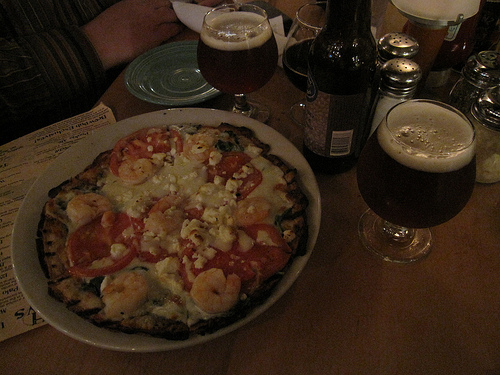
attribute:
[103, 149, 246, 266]
cheese — white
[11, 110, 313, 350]
plate — green, round, white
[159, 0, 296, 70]
napkin — folded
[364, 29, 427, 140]
shaker — pepper, salt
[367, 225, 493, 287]
table — wood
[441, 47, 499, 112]
shaker — black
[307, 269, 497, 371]
table — beige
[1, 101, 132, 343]
menu — white, paper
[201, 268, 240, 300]
shrimp — pink